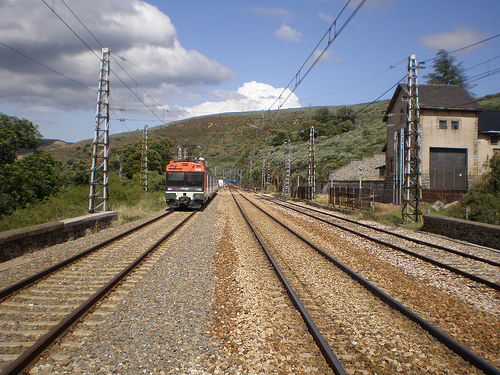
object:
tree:
[1, 111, 67, 217]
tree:
[121, 147, 165, 197]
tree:
[300, 101, 330, 139]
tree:
[330, 101, 358, 133]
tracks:
[122, 211, 173, 235]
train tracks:
[274, 265, 344, 375]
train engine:
[163, 145, 213, 212]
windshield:
[167, 170, 203, 190]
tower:
[88, 46, 114, 213]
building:
[384, 83, 497, 208]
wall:
[0, 211, 119, 258]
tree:
[427, 49, 474, 99]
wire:
[0, 0, 101, 75]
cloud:
[191, 81, 302, 118]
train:
[161, 156, 219, 212]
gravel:
[157, 262, 266, 373]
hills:
[70, 106, 276, 188]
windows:
[439, 120, 448, 130]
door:
[428, 147, 468, 205]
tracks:
[2, 296, 98, 373]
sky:
[3, 2, 500, 83]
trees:
[272, 130, 288, 146]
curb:
[420, 212, 500, 253]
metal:
[86, 238, 109, 251]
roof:
[382, 83, 484, 122]